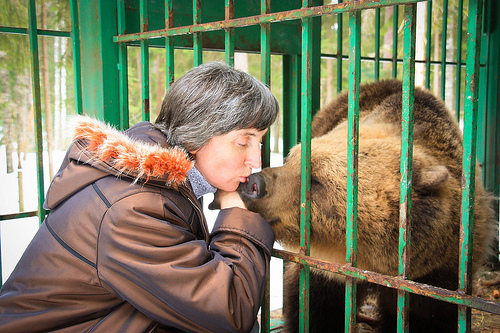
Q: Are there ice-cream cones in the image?
A: No, there are no ice-cream cones.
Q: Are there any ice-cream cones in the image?
A: No, there are no ice-cream cones.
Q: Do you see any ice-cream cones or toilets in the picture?
A: No, there are no ice-cream cones or toilets.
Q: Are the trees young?
A: Yes, the trees are young.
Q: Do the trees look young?
A: Yes, the trees are young.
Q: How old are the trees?
A: The trees are young.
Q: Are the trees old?
A: No, the trees are young.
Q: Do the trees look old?
A: No, the trees are young.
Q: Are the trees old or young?
A: The trees are young.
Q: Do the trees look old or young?
A: The trees are young.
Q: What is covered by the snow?
A: The ground is covered by the snow.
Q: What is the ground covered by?
A: The ground is covered by the snow.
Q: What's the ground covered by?
A: The ground is covered by the snow.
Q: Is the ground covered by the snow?
A: Yes, the ground is covered by the snow.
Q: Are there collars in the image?
A: Yes, there is a collar.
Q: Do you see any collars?
A: Yes, there is a collar.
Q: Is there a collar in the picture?
A: Yes, there is a collar.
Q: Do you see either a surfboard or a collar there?
A: Yes, there is a collar.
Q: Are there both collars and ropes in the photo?
A: No, there is a collar but no ropes.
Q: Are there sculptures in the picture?
A: No, there are no sculptures.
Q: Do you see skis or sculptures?
A: No, there are no sculptures or skis.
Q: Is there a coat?
A: Yes, there is a coat.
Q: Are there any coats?
A: Yes, there is a coat.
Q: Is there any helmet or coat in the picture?
A: Yes, there is a coat.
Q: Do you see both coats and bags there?
A: No, there is a coat but no bags.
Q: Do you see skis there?
A: No, there are no skis.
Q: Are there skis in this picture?
A: No, there are no skis.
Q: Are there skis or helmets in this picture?
A: No, there are no skis or helmets.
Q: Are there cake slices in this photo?
A: No, there are no cake slices.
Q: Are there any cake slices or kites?
A: No, there are no cake slices or kites.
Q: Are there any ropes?
A: No, there are no ropes.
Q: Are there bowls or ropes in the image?
A: No, there are no ropes or bowls.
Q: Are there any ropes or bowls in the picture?
A: No, there are no ropes or bowls.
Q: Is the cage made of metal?
A: Yes, the cage is made of metal.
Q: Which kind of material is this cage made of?
A: The cage is made of metal.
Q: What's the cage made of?
A: The cage is made of metal.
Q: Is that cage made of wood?
A: No, the cage is made of metal.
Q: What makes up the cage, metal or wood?
A: The cage is made of metal.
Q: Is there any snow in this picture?
A: Yes, there is snow.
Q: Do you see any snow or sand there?
A: Yes, there is snow.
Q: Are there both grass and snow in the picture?
A: No, there is snow but no grass.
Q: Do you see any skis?
A: No, there are no skis.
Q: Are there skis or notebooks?
A: No, there are no skis or notebooks.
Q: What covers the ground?
A: The snow covers the ground.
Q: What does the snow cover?
A: The snow covers the ground.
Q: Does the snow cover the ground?
A: Yes, the snow covers the ground.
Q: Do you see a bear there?
A: Yes, there is a bear.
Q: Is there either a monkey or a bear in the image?
A: Yes, there is a bear.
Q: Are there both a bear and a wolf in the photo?
A: No, there is a bear but no wolves.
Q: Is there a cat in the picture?
A: No, there are no cats.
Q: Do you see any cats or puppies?
A: No, there are no cats or puppies.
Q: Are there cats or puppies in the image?
A: No, there are no cats or puppies.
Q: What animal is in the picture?
A: The animal is a bear.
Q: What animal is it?
A: The animal is a bear.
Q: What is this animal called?
A: That is a bear.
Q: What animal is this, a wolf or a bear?
A: That is a bear.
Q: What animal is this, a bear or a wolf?
A: That is a bear.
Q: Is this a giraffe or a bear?
A: This is a bear.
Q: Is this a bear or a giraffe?
A: This is a bear.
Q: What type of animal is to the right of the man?
A: The animal is a bear.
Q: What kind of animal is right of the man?
A: The animal is a bear.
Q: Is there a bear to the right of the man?
A: Yes, there is a bear to the right of the man.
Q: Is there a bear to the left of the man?
A: No, the bear is to the right of the man.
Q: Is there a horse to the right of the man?
A: No, there is a bear to the right of the man.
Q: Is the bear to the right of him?
A: Yes, the bear is to the right of the man.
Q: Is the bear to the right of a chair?
A: No, the bear is to the right of the man.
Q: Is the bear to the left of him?
A: No, the bear is to the right of a man.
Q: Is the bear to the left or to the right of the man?
A: The bear is to the right of the man.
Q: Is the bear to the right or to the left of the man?
A: The bear is to the right of the man.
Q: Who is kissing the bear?
A: The man is kissing the bear.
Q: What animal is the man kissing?
A: The man is kissing the bear.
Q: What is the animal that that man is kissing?
A: The animal is a bear.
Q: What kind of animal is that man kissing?
A: The man is kissing the bear.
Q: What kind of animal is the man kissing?
A: The man is kissing the bear.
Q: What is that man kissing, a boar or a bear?
A: The man is kissing a bear.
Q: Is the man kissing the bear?
A: Yes, the man is kissing the bear.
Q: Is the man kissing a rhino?
A: No, the man is kissing the bear.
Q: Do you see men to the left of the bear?
A: Yes, there is a man to the left of the bear.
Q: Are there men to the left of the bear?
A: Yes, there is a man to the left of the bear.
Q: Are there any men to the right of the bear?
A: No, the man is to the left of the bear.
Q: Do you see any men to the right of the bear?
A: No, the man is to the left of the bear.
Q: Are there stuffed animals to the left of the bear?
A: No, there is a man to the left of the bear.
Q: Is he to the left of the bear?
A: Yes, the man is to the left of the bear.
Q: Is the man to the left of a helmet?
A: No, the man is to the left of the bear.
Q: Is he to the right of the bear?
A: No, the man is to the left of the bear.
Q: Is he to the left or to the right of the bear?
A: The man is to the left of the bear.